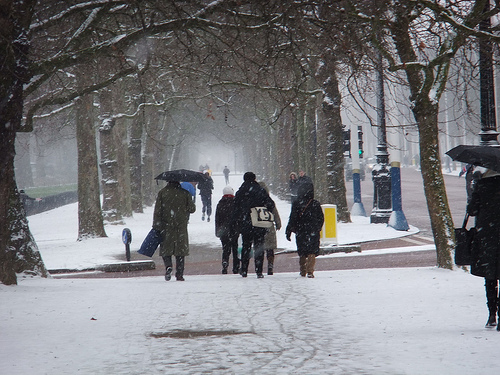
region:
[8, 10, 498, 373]
white snowflakes is falling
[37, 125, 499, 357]
people walking on the snow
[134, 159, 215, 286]
man holding a black umbrella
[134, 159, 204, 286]
man holding a long coat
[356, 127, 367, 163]
a traffic light on the street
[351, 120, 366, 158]
the traffic light is in red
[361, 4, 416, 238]
a pole on the sidewalk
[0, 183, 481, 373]
sidewalk is color white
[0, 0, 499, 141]
the trees are covered with snow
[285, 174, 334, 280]
person wears brown boots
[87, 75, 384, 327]
people walking in snow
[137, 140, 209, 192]
person holding umbrella in snow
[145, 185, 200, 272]
person wearing long trench coat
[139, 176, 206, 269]
trench coat is dark green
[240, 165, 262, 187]
person wearing black hat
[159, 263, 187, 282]
person wearing black shoes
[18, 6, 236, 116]
snow resting on branches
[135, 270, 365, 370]
walking tracks in snow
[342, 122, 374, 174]
traffic light lit green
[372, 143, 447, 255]
blue post on side of street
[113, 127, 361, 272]
people are walking on the street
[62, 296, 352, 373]
the snow is on the ground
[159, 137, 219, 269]
the man has an umbrella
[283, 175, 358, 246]
the box is yellow in colour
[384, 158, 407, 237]
the post is blue in colour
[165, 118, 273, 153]
the snow is falling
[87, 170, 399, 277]
they are carrying bags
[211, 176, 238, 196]
the hat is white in colour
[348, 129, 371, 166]
the light is green in colour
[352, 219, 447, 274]
the road hs got strippes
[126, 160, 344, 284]
four people walking on the sidewalk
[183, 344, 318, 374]
many sets of tracks in the snow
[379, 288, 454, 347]
white snow on the sidewalk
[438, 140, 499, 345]
a person carrying a black umbrella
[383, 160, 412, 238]
blue post next to the sidewalk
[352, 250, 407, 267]
red concrete surface of the path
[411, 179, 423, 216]
black asphalt of the road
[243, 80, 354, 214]
many trees growing next to the street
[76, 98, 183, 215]
many trees growing next to the sidewalk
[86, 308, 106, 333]
a fallen leaf in the snow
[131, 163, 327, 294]
group of people warmly dressed walking down a snowy sidewalk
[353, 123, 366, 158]
traffic light with a green signal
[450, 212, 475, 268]
large black purse a woman is carrying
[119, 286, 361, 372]
snow covered sidewalk full of footprints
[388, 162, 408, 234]
blue post along side of the road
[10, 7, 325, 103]
branches from a large tree next to the sidewalk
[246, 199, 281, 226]
white bag with a black face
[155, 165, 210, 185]
top of black umbrella a person is carrying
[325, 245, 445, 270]
brick path free from snow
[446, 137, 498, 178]
top of black umbrella a person is carrying